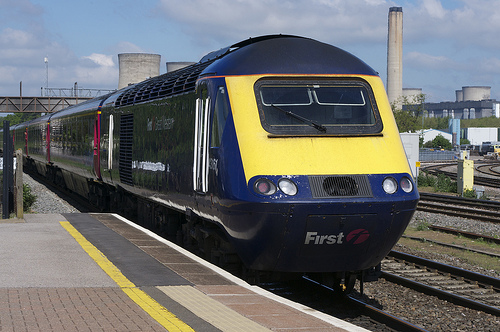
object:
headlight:
[381, 178, 397, 194]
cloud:
[0, 29, 27, 48]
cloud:
[1, 55, 115, 82]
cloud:
[152, 0, 499, 86]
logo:
[347, 226, 371, 245]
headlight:
[277, 177, 298, 196]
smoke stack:
[385, 4, 404, 111]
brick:
[0, 289, 128, 332]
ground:
[0, 276, 500, 332]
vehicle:
[481, 152, 498, 162]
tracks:
[256, 157, 500, 332]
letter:
[302, 229, 343, 245]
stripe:
[236, 280, 366, 332]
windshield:
[253, 76, 384, 137]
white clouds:
[78, 72, 114, 85]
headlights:
[252, 178, 279, 196]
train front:
[223, 71, 412, 176]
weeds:
[413, 227, 458, 254]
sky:
[1, 0, 162, 53]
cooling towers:
[116, 53, 159, 89]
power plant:
[387, 7, 496, 112]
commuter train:
[1, 33, 420, 295]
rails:
[367, 250, 499, 332]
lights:
[398, 178, 414, 193]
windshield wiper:
[269, 102, 326, 131]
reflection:
[33, 117, 168, 169]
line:
[56, 218, 190, 332]